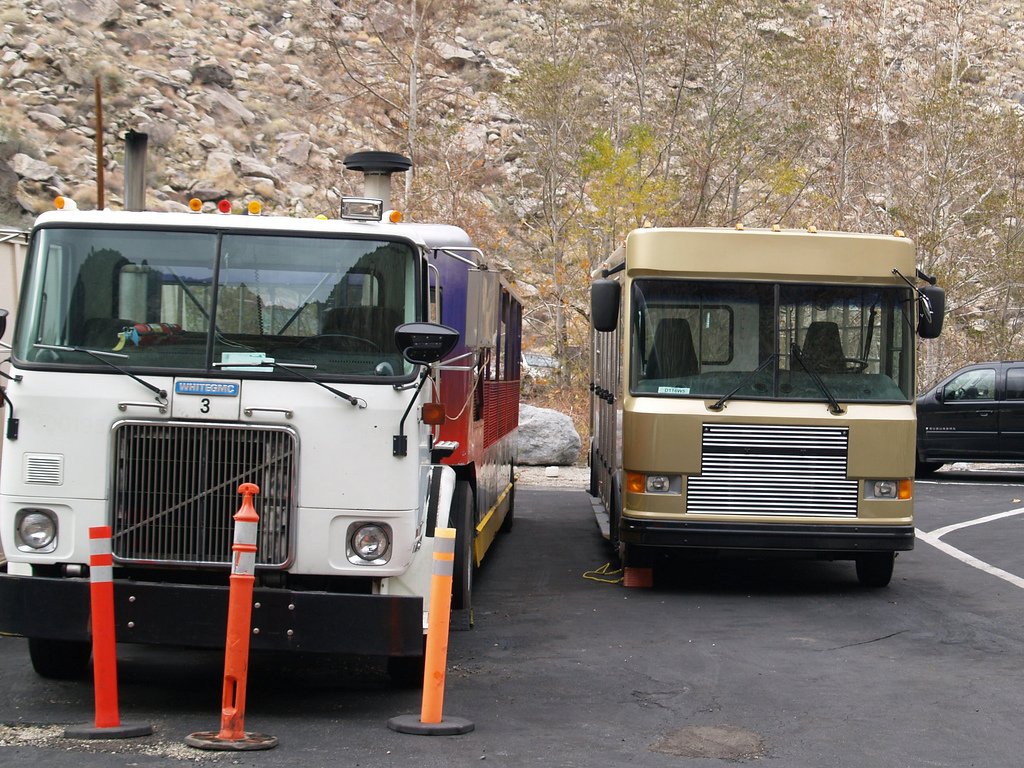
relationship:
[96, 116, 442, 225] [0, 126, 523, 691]
pipes on white truck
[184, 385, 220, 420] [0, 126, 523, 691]
number 3 on front of white truck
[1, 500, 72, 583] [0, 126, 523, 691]
headlight on white truck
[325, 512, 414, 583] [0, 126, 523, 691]
headlight on white truck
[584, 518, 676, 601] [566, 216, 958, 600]
front tire on bus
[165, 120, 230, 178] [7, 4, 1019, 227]
rock covering hill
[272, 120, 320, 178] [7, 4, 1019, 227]
rock covering hill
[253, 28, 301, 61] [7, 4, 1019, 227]
rock covering hill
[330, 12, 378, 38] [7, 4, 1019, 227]
rock covering hill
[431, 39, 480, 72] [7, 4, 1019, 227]
rock covering hill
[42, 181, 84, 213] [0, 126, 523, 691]
light on top of white truck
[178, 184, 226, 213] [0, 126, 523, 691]
light on top of white truck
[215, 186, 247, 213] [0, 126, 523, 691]
light on top of white truck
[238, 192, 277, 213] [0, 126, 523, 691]
light on top of white truck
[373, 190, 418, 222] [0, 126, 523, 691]
light on top of white truck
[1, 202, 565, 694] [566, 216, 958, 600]
white truck next to bus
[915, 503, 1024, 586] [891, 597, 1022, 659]
white line on road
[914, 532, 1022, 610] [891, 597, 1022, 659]
line on road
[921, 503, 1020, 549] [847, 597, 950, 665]
white line on road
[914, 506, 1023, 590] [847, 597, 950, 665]
line on road